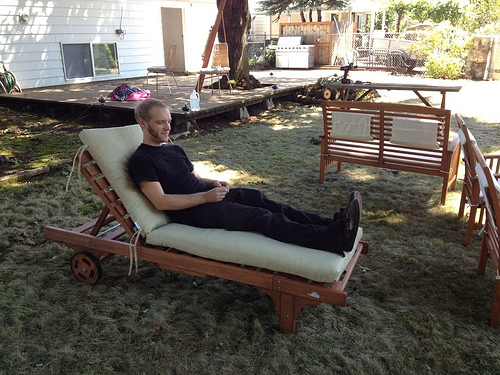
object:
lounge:
[40, 123, 368, 335]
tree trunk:
[215, 1, 251, 70]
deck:
[109, 70, 246, 96]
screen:
[63, 43, 120, 80]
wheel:
[68, 251, 101, 286]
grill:
[276, 34, 318, 70]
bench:
[319, 99, 463, 205]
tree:
[249, 0, 348, 25]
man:
[127, 97, 362, 267]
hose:
[0, 59, 21, 96]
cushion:
[146, 223, 364, 285]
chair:
[28, 150, 370, 335]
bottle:
[187, 86, 200, 112]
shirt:
[128, 142, 204, 204]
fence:
[270, 15, 478, 72]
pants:
[171, 188, 345, 260]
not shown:
[3, 3, 498, 373]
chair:
[142, 65, 184, 95]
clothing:
[126, 143, 350, 258]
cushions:
[329, 103, 445, 168]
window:
[66, 43, 92, 77]